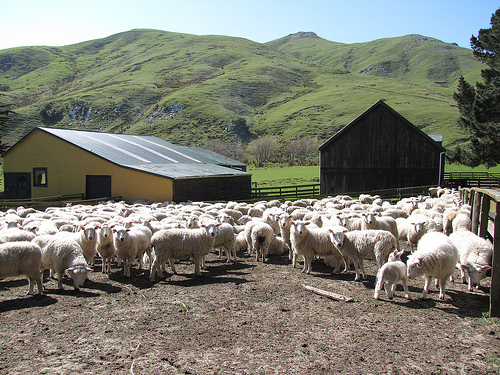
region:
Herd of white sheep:
[17, 203, 479, 303]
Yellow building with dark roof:
[10, 108, 230, 197]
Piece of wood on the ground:
[292, 277, 371, 313]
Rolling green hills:
[60, 19, 410, 104]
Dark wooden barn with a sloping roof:
[312, 94, 441, 191]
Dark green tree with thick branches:
[450, 15, 499, 158]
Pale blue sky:
[348, 6, 479, 27]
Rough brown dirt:
[101, 300, 337, 373]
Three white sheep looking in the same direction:
[80, 218, 139, 244]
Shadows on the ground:
[412, 291, 484, 318]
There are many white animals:
[46, 198, 491, 297]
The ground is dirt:
[176, 280, 298, 350]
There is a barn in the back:
[24, 118, 240, 265]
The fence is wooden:
[235, 142, 499, 309]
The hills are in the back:
[74, 12, 429, 150]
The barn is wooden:
[322, 109, 462, 246]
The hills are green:
[202, 40, 411, 160]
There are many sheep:
[92, 228, 495, 349]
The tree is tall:
[444, 7, 498, 188]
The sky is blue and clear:
[202, 2, 439, 91]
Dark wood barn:
[317, 98, 444, 197]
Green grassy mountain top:
[274, 28, 444, 65]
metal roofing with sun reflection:
[106, 133, 162, 163]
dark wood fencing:
[252, 181, 313, 196]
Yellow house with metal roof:
[0, 123, 172, 203]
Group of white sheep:
[104, 200, 169, 226]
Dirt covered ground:
[189, 304, 328, 374]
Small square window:
[33, 167, 47, 185]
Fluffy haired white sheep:
[146, 219, 218, 276]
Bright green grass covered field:
[250, 166, 316, 180]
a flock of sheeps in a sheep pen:
[0, 196, 499, 368]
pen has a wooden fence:
[456, 176, 498, 236]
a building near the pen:
[6, 113, 258, 204]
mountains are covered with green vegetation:
[1, 23, 496, 115]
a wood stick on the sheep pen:
[294, 279, 355, 310]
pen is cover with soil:
[0, 281, 499, 372]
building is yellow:
[9, 114, 259, 212]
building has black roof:
[5, 108, 255, 189]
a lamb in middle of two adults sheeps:
[367, 243, 417, 308]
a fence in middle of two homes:
[249, 173, 321, 200]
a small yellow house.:
[0, 126, 256, 216]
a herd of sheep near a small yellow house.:
[0, 181, 490, 298]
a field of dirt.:
[0, 251, 499, 372]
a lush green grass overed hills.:
[0, 22, 497, 169]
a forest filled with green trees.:
[0, 116, 492, 183]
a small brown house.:
[315, 99, 447, 193]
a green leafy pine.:
[453, 7, 498, 169]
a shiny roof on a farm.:
[35, 129, 249, 173]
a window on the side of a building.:
[26, 165, 51, 196]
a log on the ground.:
[290, 274, 357, 304]